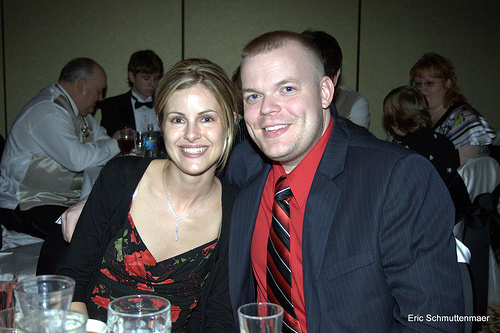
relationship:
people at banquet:
[0, 31, 496, 332] [0, 122, 499, 331]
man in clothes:
[54, 29, 466, 331] [218, 111, 466, 333]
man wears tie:
[54, 29, 466, 331] [266, 174, 302, 333]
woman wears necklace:
[57, 58, 246, 332] [159, 156, 219, 243]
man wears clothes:
[54, 29, 466, 331] [218, 111, 466, 333]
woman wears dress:
[57, 58, 246, 332] [88, 209, 219, 329]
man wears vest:
[1, 56, 132, 291] [0, 83, 96, 213]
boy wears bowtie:
[92, 47, 165, 137] [128, 92, 155, 110]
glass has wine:
[115, 126, 136, 154] [116, 135, 135, 153]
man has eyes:
[54, 29, 466, 331] [249, 85, 292, 100]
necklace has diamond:
[159, 156, 219, 243] [172, 232, 179, 240]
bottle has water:
[139, 124, 157, 159] [145, 135, 154, 155]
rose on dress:
[123, 249, 156, 280] [88, 209, 219, 329]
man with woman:
[54, 29, 466, 331] [57, 58, 246, 332]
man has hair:
[54, 29, 466, 331] [240, 31, 327, 83]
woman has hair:
[57, 58, 246, 332] [152, 56, 240, 177]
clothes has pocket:
[218, 111, 466, 333] [320, 246, 389, 329]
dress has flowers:
[88, 209, 219, 329] [103, 233, 175, 292]